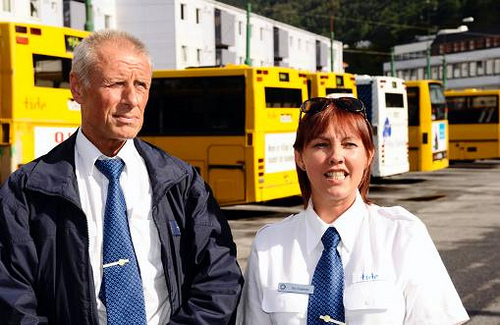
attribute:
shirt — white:
[247, 198, 469, 323]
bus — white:
[352, 71, 416, 184]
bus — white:
[190, 66, 270, 201]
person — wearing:
[240, 86, 461, 322]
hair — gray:
[68, 42, 93, 72]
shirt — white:
[239, 191, 465, 323]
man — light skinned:
[6, 33, 228, 321]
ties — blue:
[89, 155, 346, 322]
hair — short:
[70, 27, 155, 131]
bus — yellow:
[129, 63, 311, 208]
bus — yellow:
[144, 65, 314, 208]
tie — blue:
[304, 224, 354, 324]